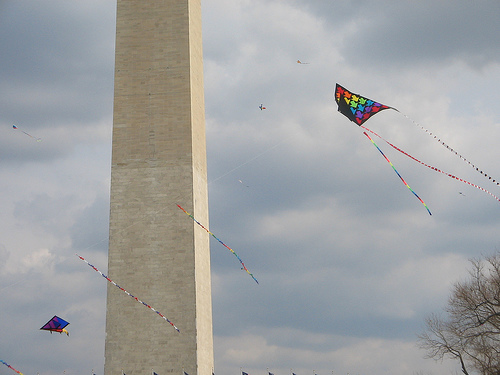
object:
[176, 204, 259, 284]
kite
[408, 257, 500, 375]
tree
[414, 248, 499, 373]
branches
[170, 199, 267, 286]
tail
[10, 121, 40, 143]
kite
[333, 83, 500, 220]
kite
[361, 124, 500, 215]
kite tail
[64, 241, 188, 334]
kite tail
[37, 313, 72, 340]
kite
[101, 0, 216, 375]
building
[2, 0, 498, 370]
sky